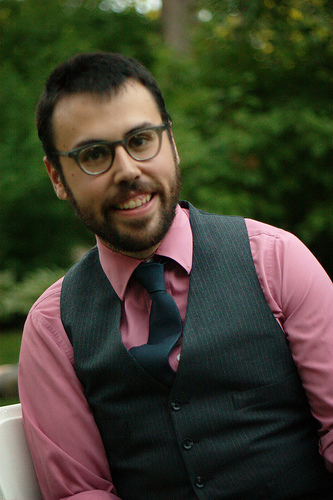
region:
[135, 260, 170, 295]
the knot of the tie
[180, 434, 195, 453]
a black button of the vest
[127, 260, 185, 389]
a black neck tie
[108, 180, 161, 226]
the mouth of the man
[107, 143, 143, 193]
the nose of the man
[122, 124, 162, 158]
the eye of the man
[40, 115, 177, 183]
a pair of glasses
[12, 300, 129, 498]
the arm of the man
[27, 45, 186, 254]
the head of a man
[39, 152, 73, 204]
the ear of the man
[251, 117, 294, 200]
There are dark green trees in the background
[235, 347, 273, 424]
This man is wearing a vest that has pinstripes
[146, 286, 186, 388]
This man is wearing a tie that looks navy in color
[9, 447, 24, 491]
The bench upon which the man is sitting is white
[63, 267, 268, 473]
This photo was taken on the occasion of a wedding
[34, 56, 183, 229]
The man has a dark brown beard and hair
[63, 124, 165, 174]
This man has dark brown glasses on his face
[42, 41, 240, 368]
This man's name is Mr. Sidney Hudson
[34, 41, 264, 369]
This photo was taken in the city of Massachusetts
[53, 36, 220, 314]
This photo won an award for its composition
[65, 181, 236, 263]
A man is smiling.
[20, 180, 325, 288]
The man is outside.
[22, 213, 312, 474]
The man is sitting.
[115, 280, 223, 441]
The man is wearing a tie.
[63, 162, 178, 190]
The man is wearing glasses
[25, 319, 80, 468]
The man's shirt is purple.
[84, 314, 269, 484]
The man is wearing a black vest.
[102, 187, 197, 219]
The man is smiling.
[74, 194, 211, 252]
The man has a short beard.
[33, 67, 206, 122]
The man has short hair.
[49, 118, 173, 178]
The glasses on the man's face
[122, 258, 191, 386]
The man's black tie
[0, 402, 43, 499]
The white chair the man is on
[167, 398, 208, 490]
The buttons on the man's vest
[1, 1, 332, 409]
The trees behind the man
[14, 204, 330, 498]
The pink shirt of the man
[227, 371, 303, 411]
The pocket on the vest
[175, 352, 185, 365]
The white pocket on the pink shirt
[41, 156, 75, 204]
The man's right ear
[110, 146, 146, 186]
The man's nose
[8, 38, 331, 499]
Man is smiling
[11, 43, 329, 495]
Man wears long sleeve shirt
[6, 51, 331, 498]
Boy wears pink shirt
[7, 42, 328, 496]
Man wears a pink shirt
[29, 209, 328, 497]
Black vest on pink shirt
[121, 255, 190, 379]
Tie under pink collar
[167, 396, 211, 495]
Buttons on vest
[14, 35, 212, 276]
Man wears black glasses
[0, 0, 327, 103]
Green trees on back of man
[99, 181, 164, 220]
Front teeth